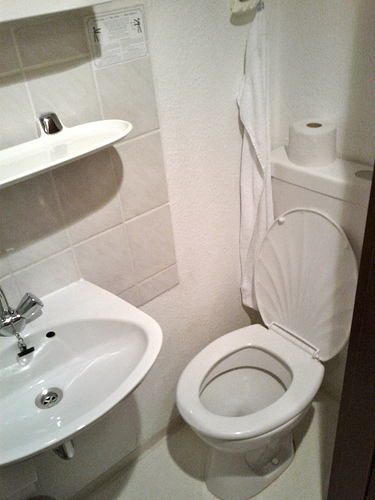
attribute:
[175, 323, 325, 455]
toilet bowl — Clean 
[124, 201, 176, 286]
tile — Grey 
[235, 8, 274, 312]
towel — White , hanging 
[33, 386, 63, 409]
drain — Clean 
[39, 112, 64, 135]
fixture — Metal 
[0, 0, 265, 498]
wall — White 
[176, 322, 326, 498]
toilet bowl — White , porcelain 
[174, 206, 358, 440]
toilet seat — white , plastic 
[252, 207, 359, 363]
lid — plastic , white 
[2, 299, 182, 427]
bathroom sink — white, porcelain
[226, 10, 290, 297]
towel — hanging, white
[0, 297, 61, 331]
bathroom faucet — chrome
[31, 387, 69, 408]
sink drain — chrome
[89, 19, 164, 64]
warning sticker — white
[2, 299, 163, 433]
bathroom sink — porcelain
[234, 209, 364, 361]
lid — open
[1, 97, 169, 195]
counter shelf — small, white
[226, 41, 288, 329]
towel — white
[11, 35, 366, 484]
bathroom — white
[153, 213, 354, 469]
toilet — small, white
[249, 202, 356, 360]
lid — open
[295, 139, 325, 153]
toilet paper — white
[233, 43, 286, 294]
towel — white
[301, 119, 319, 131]
roll — full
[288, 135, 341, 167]
toilet paper — white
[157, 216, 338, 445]
toilet — clean, white, porcelain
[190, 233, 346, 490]
toilet — white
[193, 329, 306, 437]
seat — white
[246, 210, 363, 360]
lid — white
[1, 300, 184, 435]
sink — white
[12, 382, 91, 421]
drain — shiny, small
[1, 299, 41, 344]
faucet — silver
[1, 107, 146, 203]
shelf — white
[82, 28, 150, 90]
sign — white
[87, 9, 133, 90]
stick figures — black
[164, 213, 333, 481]
toilet — white, ceramic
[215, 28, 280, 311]
towel — white